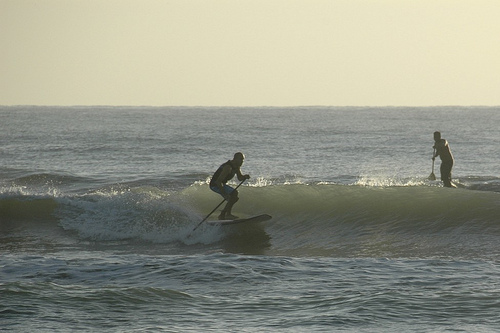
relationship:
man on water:
[208, 149, 252, 221] [0, 107, 498, 330]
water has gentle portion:
[0, 107, 498, 330] [0, 105, 500, 187]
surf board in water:
[201, 213, 274, 226] [0, 183, 500, 330]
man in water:
[208, 149, 252, 221] [0, 107, 498, 330]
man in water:
[427, 129, 454, 189] [0, 107, 498, 330]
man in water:
[422, 127, 466, 189] [0, 107, 498, 330]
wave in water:
[1, 181, 498, 258] [0, 107, 498, 330]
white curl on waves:
[356, 169, 413, 189] [0, 176, 500, 256]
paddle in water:
[189, 174, 248, 233] [0, 107, 498, 330]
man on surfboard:
[427, 129, 454, 189] [443, 182, 456, 186]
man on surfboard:
[208, 149, 252, 221] [206, 215, 270, 225]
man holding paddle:
[427, 129, 454, 189] [428, 145, 439, 178]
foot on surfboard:
[218, 213, 231, 221] [209, 152, 249, 219]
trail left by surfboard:
[65, 185, 223, 247] [198, 210, 271, 230]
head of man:
[231, 150, 245, 167] [202, 148, 258, 223]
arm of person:
[212, 162, 234, 192] [205, 148, 252, 224]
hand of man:
[243, 174, 250, 179] [208, 149, 252, 221]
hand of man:
[226, 194, 231, 199] [208, 149, 252, 221]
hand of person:
[431, 156, 437, 161] [431, 131, 455, 186]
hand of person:
[431, 145, 437, 149] [431, 131, 455, 186]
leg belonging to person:
[211, 185, 237, 220] [192, 127, 237, 216]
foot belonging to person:
[224, 213, 238, 221] [203, 143, 255, 218]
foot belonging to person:
[218, 213, 225, 220] [203, 143, 255, 218]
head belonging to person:
[432, 130, 442, 142] [433, 130, 455, 195]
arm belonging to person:
[431, 149, 440, 162] [422, 117, 482, 209]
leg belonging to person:
[214, 186, 237, 220] [196, 151, 264, 216]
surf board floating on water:
[205, 207, 287, 228] [0, 107, 498, 330]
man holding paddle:
[208, 149, 252, 221] [184, 174, 247, 236]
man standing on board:
[208, 149, 252, 221] [207, 211, 275, 227]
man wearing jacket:
[208, 149, 250, 221] [204, 159, 249, 183]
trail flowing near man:
[56, 185, 229, 246] [186, 117, 311, 237]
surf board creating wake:
[201, 213, 274, 226] [60, 192, 225, 242]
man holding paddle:
[427, 129, 454, 189] [428, 141, 438, 177]